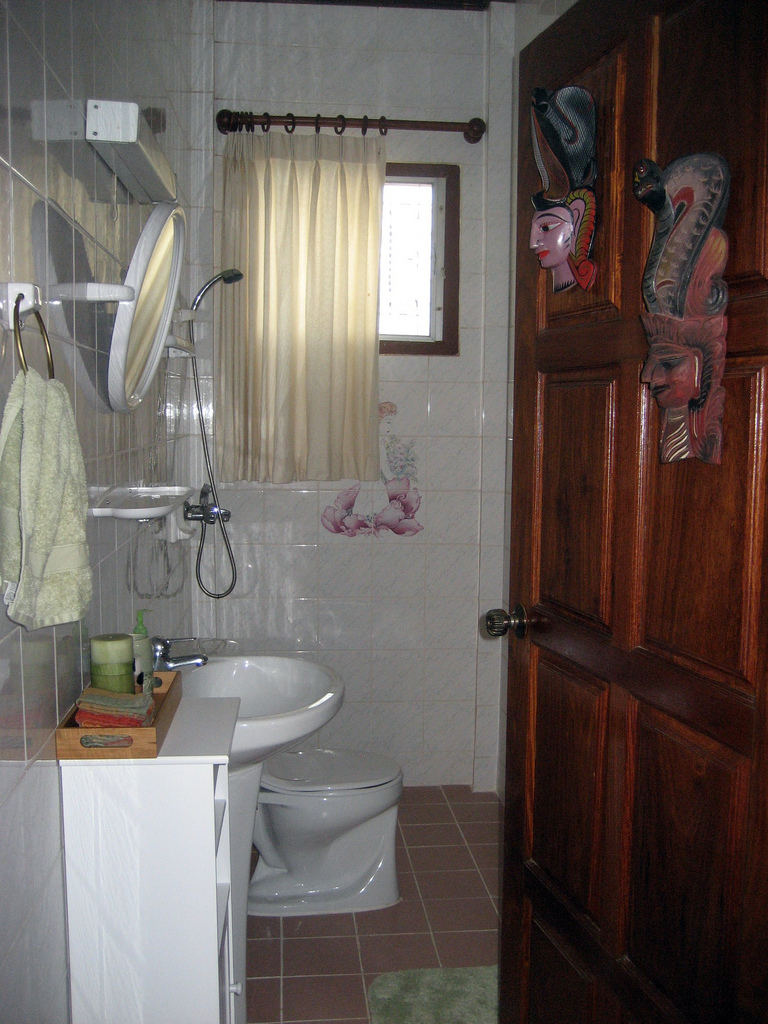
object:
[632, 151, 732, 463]
mask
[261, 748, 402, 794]
toilet lid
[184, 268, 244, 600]
shower head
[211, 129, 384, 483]
curtain panel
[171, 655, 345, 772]
bathroom sink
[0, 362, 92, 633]
towel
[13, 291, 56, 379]
towel ring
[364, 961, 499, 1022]
bath mat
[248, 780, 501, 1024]
floor